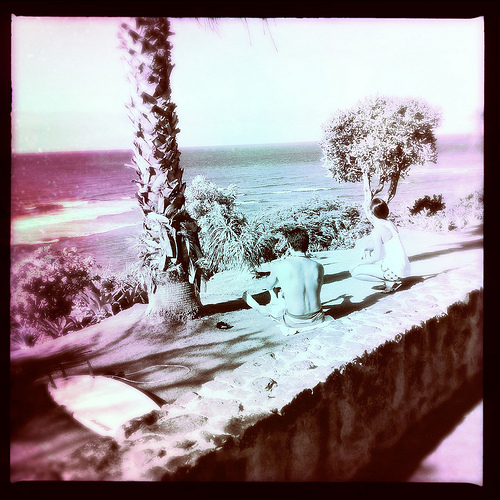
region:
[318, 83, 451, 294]
a tree by the water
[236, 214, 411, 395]
a person sittin gdown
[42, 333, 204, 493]
a surfboard on teh ground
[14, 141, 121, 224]
a body of water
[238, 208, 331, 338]
Man sitting on the beach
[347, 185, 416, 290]
woman sitting on the beach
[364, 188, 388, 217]
woman with black hair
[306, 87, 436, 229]
tree on the beach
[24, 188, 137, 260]
water washing on shore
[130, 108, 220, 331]
tree on the beach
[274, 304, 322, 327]
man wearing shorts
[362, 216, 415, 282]
woman wearing a white shirt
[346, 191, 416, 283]
woman crouched down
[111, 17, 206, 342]
Tall trunk of a palm tree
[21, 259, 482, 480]
Low wall made of concrete and stone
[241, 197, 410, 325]
Two people sitting together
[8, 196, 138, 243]
Small waves breaking in the ocean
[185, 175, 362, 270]
Short bushes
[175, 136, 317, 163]
The horizon over the smooth ocean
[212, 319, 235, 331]
One sandal sitting on the ground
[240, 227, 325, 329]
A guy without a shirt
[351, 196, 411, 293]
Woman in a tank top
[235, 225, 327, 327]
Man in shorts near a tree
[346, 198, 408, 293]
A woman crouching beside a man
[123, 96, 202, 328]
Palm tree trunk near a man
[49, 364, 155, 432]
White surfboard on sand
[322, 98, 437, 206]
A tree near a beach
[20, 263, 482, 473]
A stone wall behind people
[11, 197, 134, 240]
Water moving in the ocean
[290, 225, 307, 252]
Dark brown hair on a man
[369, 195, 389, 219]
Brown hair on a woman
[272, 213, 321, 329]
a person sitting down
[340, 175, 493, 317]
a person squating outside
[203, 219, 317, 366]
a person sitting on the beach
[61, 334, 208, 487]
a surfboard on teh beach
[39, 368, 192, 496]
a surfbaord on the sand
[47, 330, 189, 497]
a surfboard laying on the sand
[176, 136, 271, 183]
a body of water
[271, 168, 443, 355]
two people on beach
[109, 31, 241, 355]
trunk of tall palm tree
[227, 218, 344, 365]
boy sitting on the sand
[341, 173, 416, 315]
Girl knelt on the ground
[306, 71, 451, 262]
Tree on the beach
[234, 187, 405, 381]
A man and woman sitting on the beach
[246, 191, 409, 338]
A man and woman setting on the beach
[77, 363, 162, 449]
A surfboard lying on the ground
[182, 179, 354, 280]
Palm tree by the beach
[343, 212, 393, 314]
A woman with a tank top on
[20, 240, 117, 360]
A bush by the beach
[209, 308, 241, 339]
Sunglasses on the ground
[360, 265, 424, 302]
Woman with flip-flops on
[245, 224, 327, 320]
a man sitting on the ground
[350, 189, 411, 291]
a woman kneeling on the ground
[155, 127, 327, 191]
a large body of water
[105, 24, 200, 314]
the trunk of a palm tree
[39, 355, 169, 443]
a surf board on the ground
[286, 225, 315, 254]
a man with dark hair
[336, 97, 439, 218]
a small tree near the water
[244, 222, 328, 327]
A man sitting down by the water.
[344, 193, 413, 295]
A woman sitting down by the water.